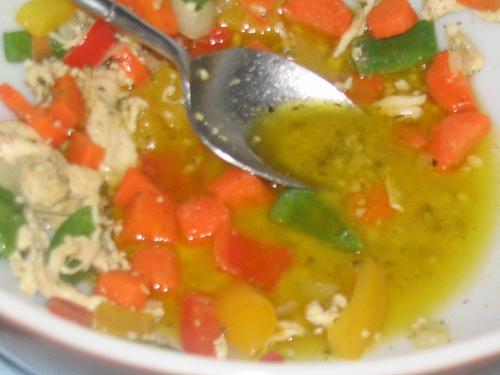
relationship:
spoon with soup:
[39, 65, 381, 196] [48, 4, 498, 341]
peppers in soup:
[341, 22, 447, 79] [6, 2, 496, 368]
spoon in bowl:
[66, 0, 371, 190] [0, 0, 500, 374]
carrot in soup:
[197, 155, 280, 217] [6, 2, 496, 368]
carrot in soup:
[102, 159, 174, 202] [6, 2, 496, 368]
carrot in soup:
[170, 190, 242, 243] [6, 2, 496, 368]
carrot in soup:
[112, 186, 193, 249] [6, 2, 496, 368]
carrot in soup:
[132, 245, 189, 299] [6, 2, 496, 368]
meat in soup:
[2, 28, 167, 320] [6, 2, 496, 368]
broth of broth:
[129, 5, 498, 358] [101, 0, 498, 359]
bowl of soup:
[0, 0, 500, 374] [4, 6, 484, 312]